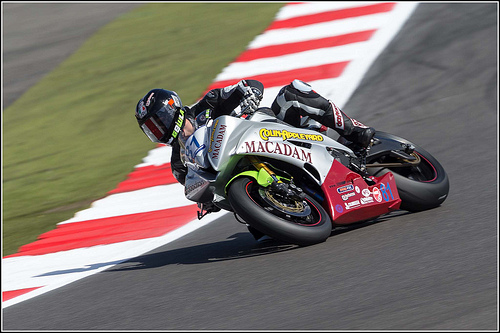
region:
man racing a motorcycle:
[131, 74, 454, 240]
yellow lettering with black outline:
[254, 122, 331, 145]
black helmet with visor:
[138, 90, 185, 145]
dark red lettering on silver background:
[240, 139, 315, 164]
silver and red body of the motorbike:
[205, 112, 397, 223]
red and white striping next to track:
[0, 5, 390, 323]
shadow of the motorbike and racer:
[31, 225, 278, 274]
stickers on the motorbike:
[332, 170, 395, 211]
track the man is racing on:
[39, 5, 499, 332]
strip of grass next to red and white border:
[5, 1, 268, 238]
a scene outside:
[9, 5, 490, 325]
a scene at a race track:
[6, 2, 498, 324]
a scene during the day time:
[6, 8, 497, 326]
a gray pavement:
[43, 5, 497, 326]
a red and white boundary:
[3, 6, 438, 331]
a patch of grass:
[0, 0, 294, 264]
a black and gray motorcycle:
[119, 63, 463, 253]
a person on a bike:
[107, 58, 464, 268]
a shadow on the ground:
[27, 201, 325, 292]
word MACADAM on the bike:
[230, 125, 321, 175]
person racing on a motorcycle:
[136, 80, 448, 241]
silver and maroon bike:
[169, 105, 453, 233]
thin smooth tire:
[220, 170, 339, 247]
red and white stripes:
[25, 13, 387, 316]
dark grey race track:
[128, 12, 498, 324]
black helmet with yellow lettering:
[133, 85, 187, 147]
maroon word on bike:
[241, 134, 312, 161]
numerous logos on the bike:
[317, 162, 402, 221]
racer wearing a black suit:
[126, 85, 264, 190]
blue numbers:
[174, 137, 207, 159]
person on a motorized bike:
[114, 63, 469, 273]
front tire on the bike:
[217, 173, 337, 242]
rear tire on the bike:
[363, 145, 453, 212]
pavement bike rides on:
[396, 38, 491, 314]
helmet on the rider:
[121, 90, 186, 141]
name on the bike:
[240, 132, 319, 172]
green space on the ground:
[21, 97, 98, 168]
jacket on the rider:
[180, 74, 260, 196]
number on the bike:
[177, 135, 222, 176]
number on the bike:
[376, 169, 396, 229]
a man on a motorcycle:
[116, 67, 488, 258]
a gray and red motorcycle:
[215, 110, 421, 225]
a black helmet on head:
[113, 62, 205, 169]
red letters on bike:
[241, 133, 313, 164]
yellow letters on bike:
[257, 117, 334, 144]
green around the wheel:
[214, 167, 286, 203]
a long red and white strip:
[3, 0, 395, 293]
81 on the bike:
[168, 123, 225, 178]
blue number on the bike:
[179, 120, 221, 169]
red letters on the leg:
[311, 87, 349, 139]